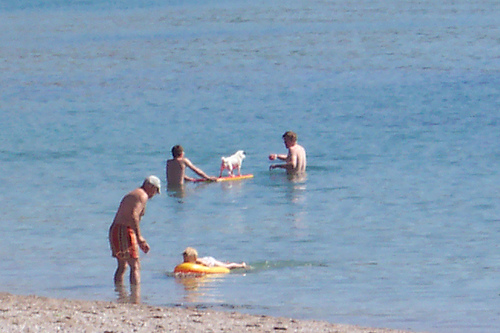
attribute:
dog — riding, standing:
[216, 145, 243, 175]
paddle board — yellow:
[195, 161, 256, 190]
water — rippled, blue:
[2, 5, 495, 326]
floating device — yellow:
[173, 256, 232, 279]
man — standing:
[96, 172, 171, 305]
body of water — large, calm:
[2, 3, 497, 329]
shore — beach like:
[3, 288, 433, 331]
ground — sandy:
[1, 286, 409, 332]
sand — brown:
[35, 308, 150, 332]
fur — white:
[229, 158, 236, 164]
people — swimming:
[99, 118, 326, 311]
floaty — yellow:
[174, 259, 233, 277]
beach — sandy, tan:
[4, 305, 426, 328]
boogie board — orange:
[209, 173, 255, 184]